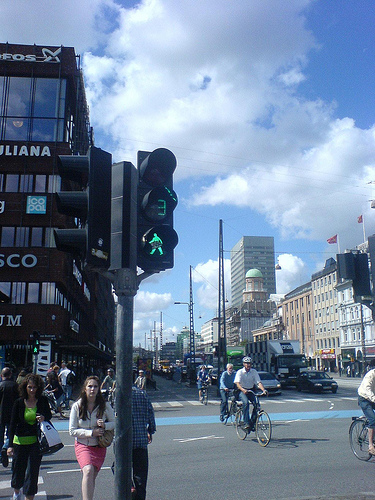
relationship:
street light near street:
[52, 139, 183, 283] [1, 398, 373, 493]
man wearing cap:
[234, 356, 269, 432] [241, 355, 253, 365]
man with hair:
[234, 356, 269, 432] [223, 360, 233, 372]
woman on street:
[67, 373, 117, 498] [0, 393, 374, 499]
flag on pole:
[326, 234, 339, 244] [334, 231, 341, 254]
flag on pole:
[354, 213, 364, 223] [360, 212, 363, 244]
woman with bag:
[67, 373, 117, 498] [34, 427, 68, 458]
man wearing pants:
[234, 356, 269, 432] [228, 386, 275, 441]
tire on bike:
[348, 419, 372, 460] [347, 412, 374, 462]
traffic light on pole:
[132, 145, 179, 273] [105, 147, 139, 497]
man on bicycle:
[234, 356, 269, 432] [230, 387, 278, 440]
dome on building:
[242, 263, 272, 301] [234, 266, 282, 345]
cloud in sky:
[97, 4, 317, 153] [6, 2, 372, 325]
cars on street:
[207, 336, 284, 430] [0, 370, 375, 498]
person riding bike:
[355, 361, 374, 439] [347, 412, 374, 462]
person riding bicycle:
[136, 368, 149, 391] [235, 390, 272, 445]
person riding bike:
[192, 361, 211, 389] [215, 399, 239, 426]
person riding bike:
[215, 357, 236, 393] [196, 379, 214, 402]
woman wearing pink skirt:
[67, 373, 117, 498] [72, 439, 107, 470]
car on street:
[294, 369, 339, 397] [157, 399, 365, 497]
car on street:
[254, 371, 282, 395] [157, 399, 365, 497]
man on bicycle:
[234, 356, 266, 439] [235, 390, 272, 445]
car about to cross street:
[254, 367, 281, 395] [52, 357, 373, 490]